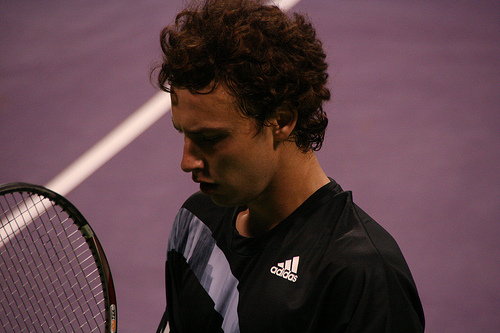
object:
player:
[157, 0, 424, 328]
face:
[171, 80, 271, 207]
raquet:
[3, 180, 116, 332]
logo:
[272, 255, 305, 281]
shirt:
[167, 180, 427, 331]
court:
[2, 3, 499, 332]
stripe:
[168, 204, 242, 332]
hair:
[154, 2, 331, 156]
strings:
[2, 189, 108, 331]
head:
[154, 3, 331, 210]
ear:
[275, 98, 302, 141]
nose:
[178, 137, 209, 175]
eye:
[200, 135, 218, 147]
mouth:
[191, 174, 221, 192]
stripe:
[0, 0, 304, 249]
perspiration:
[149, 3, 329, 154]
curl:
[157, 67, 184, 100]